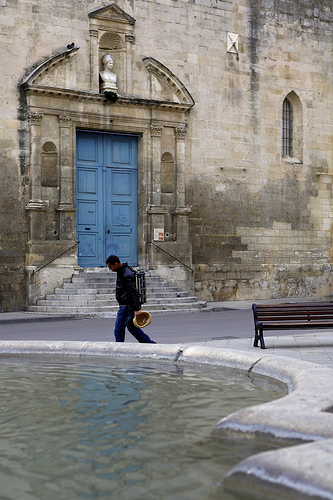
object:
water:
[0, 350, 333, 500]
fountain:
[0, 344, 331, 500]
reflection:
[74, 366, 149, 484]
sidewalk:
[0, 296, 333, 348]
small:
[54, 382, 275, 500]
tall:
[72, 126, 138, 274]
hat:
[133, 310, 153, 328]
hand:
[134, 310, 141, 319]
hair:
[106, 255, 121, 266]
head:
[106, 255, 122, 273]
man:
[106, 254, 157, 346]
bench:
[252, 294, 333, 351]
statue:
[100, 53, 118, 95]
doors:
[76, 130, 138, 269]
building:
[0, 0, 333, 322]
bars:
[281, 98, 291, 160]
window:
[278, 91, 306, 160]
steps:
[28, 264, 205, 316]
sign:
[154, 228, 165, 241]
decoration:
[99, 54, 118, 94]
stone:
[231, 248, 244, 261]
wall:
[125, 14, 333, 284]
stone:
[238, 235, 255, 241]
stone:
[274, 223, 288, 229]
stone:
[277, 228, 291, 237]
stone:
[306, 193, 322, 208]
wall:
[1, 14, 92, 271]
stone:
[279, 228, 295, 237]